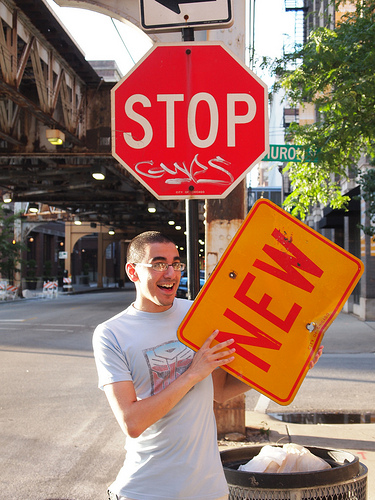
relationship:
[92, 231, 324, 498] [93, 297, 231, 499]
man wearing a shirt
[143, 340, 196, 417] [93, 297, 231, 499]
transformer on shirt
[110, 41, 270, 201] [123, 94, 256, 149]
sign says stop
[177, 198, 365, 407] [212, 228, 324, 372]
sign says new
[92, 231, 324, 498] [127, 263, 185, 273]
man wearing glasses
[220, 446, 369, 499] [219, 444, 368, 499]
trash can made of metal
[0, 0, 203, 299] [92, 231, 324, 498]
bridge above man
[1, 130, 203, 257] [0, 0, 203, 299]
lights under bridge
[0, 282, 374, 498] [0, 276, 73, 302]
road has barricades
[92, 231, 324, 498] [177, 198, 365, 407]
man holding sign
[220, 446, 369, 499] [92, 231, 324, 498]
trash can next to man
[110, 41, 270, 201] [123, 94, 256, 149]
sign that says stop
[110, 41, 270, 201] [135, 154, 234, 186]
sign that has graffiti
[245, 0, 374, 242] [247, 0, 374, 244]
tree has leaves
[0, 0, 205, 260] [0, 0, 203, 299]
beams under bridge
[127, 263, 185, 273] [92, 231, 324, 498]
glasses on man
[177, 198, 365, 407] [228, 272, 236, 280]
sign has a hole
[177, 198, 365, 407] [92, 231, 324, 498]
sign held by man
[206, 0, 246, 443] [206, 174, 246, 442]
post has rust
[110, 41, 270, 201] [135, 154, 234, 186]
sign has graffiti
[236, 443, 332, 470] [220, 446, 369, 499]
trash in trash can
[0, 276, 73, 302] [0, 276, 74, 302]
barricades have color white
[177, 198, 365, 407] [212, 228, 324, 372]
sign that says new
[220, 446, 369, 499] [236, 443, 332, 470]
trash can has trash